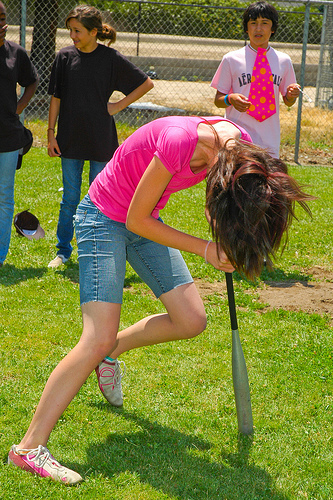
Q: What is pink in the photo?
A: The girl's shirt.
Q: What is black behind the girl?
A: The girl's shirt.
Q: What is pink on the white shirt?
A: A tie.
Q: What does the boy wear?
A: A pink tie.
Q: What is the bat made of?
A: Steel.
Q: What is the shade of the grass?
A: Green.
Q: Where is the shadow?
A: On the yard.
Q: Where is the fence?
A: Behind the kids.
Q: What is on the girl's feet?
A: Tennis shoes.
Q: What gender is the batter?
A: Female.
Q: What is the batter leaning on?
A: Bat.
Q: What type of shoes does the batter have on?
A: Sneakers.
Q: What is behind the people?
A: Fence.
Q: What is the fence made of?
A: Metal.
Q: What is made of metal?
A: The bat.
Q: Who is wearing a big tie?
A: Person on the right.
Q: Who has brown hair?
A: Woman holding bat.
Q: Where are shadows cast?
A: On grass.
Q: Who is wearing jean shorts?
A: Woman in pink.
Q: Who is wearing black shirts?
A: Two people on the left.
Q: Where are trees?
A: In the distance.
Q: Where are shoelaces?
A: On sneakers.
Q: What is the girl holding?
A: Baseball bat.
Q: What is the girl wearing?
A: Cutoff jean shorts.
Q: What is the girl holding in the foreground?
A: A baseball bat.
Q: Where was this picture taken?
A: A field.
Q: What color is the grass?
A: Green.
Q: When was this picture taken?
A: Daytime.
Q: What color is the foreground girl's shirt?
A: Pink.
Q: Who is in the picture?
A: Girls and guys.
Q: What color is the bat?
A: Silver.